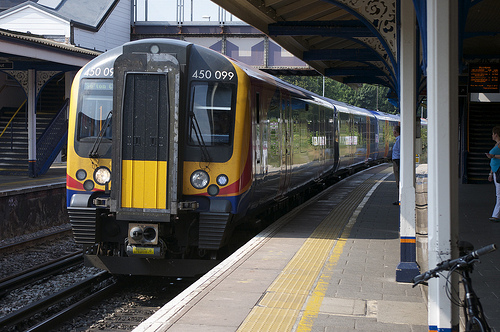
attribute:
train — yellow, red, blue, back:
[65, 36, 402, 275]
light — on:
[93, 166, 112, 185]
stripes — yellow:
[244, 164, 394, 331]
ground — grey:
[133, 164, 500, 331]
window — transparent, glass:
[189, 80, 233, 144]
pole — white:
[423, 0, 459, 330]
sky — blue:
[133, 0, 243, 23]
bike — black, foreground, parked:
[410, 236, 499, 330]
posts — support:
[394, 0, 464, 331]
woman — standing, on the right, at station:
[484, 124, 499, 220]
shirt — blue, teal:
[484, 145, 499, 170]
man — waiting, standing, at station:
[389, 124, 404, 206]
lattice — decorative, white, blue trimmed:
[327, 0, 401, 86]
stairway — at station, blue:
[0, 70, 70, 175]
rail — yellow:
[0, 99, 26, 141]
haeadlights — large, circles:
[92, 166, 209, 189]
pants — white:
[492, 172, 499, 217]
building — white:
[1, 0, 136, 52]